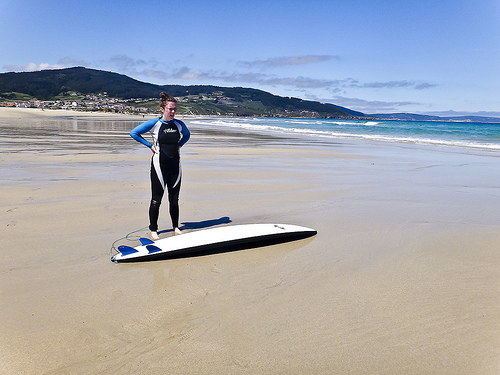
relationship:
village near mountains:
[18, 78, 139, 114] [36, 65, 336, 118]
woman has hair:
[109, 75, 199, 222] [151, 93, 177, 114]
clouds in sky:
[152, 29, 381, 100] [365, 5, 467, 96]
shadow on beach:
[170, 214, 231, 228] [284, 150, 458, 231]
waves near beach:
[259, 107, 432, 141] [284, 150, 458, 231]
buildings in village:
[55, 94, 113, 109] [18, 78, 139, 114]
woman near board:
[109, 75, 199, 222] [127, 219, 327, 272]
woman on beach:
[109, 75, 199, 222] [284, 150, 458, 231]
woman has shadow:
[109, 75, 199, 222] [170, 214, 231, 228]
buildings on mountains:
[55, 94, 113, 109] [0, 65, 369, 117]